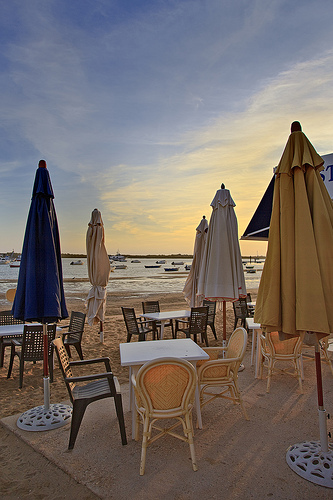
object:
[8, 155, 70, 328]
umbrella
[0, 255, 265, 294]
harbor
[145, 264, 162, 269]
boat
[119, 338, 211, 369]
table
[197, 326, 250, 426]
chairs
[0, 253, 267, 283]
water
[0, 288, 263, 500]
sand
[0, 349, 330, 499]
patio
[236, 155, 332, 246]
tent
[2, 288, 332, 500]
beach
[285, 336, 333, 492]
stand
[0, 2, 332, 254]
sky